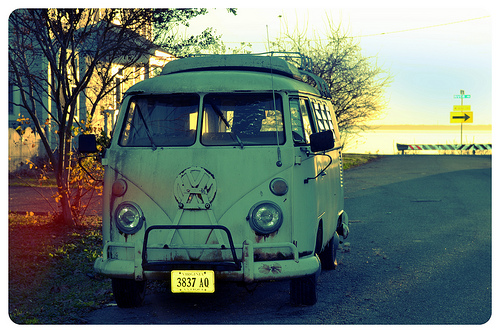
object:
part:
[444, 195, 490, 304]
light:
[254, 204, 281, 232]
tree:
[6, 4, 239, 227]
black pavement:
[87, 167, 492, 333]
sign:
[450, 111, 474, 122]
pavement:
[88, 155, 490, 323]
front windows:
[118, 92, 285, 148]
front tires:
[290, 254, 320, 306]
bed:
[8, 226, 116, 325]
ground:
[0, 154, 500, 333]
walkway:
[7, 185, 103, 217]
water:
[344, 130, 492, 154]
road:
[93, 153, 490, 325]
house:
[8, 8, 179, 176]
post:
[459, 89, 464, 143]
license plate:
[171, 270, 216, 294]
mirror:
[310, 130, 335, 153]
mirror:
[78, 134, 97, 153]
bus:
[93, 51, 348, 308]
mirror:
[306, 124, 338, 155]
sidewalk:
[8, 181, 103, 217]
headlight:
[116, 206, 140, 230]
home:
[8, 8, 177, 172]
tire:
[112, 274, 145, 308]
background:
[285, 39, 481, 225]